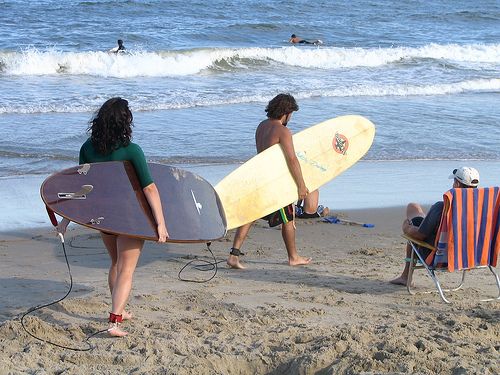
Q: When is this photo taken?
A: Daytime.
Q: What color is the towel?
A: Orange and blue.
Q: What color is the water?
A: Blue.